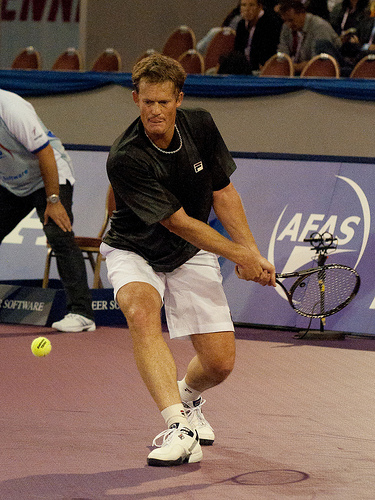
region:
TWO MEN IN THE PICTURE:
[8, 53, 261, 354]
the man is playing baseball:
[46, 79, 294, 434]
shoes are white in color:
[161, 396, 220, 456]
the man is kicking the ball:
[28, 151, 255, 354]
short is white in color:
[109, 244, 242, 342]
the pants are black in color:
[8, 192, 97, 265]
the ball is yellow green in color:
[30, 334, 78, 377]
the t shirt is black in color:
[144, 186, 235, 236]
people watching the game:
[233, 4, 356, 76]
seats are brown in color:
[276, 56, 332, 73]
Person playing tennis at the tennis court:
[95, 52, 361, 469]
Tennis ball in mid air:
[26, 334, 54, 358]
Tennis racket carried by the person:
[275, 260, 362, 319]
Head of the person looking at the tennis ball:
[128, 54, 189, 137]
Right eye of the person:
[140, 97, 155, 105]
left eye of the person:
[155, 97, 172, 105]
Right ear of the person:
[129, 89, 138, 104]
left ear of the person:
[174, 92, 184, 107]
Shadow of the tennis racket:
[205, 464, 313, 489]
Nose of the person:
[150, 102, 160, 115]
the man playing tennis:
[102, 54, 365, 470]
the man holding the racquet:
[96, 49, 374, 471]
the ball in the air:
[22, 329, 56, 363]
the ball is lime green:
[26, 333, 53, 360]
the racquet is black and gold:
[274, 262, 365, 325]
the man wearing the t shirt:
[95, 97, 250, 277]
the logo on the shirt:
[185, 157, 207, 175]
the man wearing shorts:
[96, 234, 238, 344]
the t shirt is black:
[106, 99, 237, 270]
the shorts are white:
[102, 236, 233, 339]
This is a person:
[113, 45, 294, 465]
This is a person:
[1, 82, 116, 360]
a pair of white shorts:
[97, 242, 235, 340]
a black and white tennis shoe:
[144, 425, 203, 467]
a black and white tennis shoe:
[175, 382, 215, 444]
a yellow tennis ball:
[29, 337, 50, 357]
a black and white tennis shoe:
[51, 313, 97, 332]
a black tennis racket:
[276, 266, 359, 317]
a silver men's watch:
[44, 193, 59, 205]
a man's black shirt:
[103, 109, 238, 277]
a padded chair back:
[12, 45, 41, 69]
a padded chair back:
[52, 48, 83, 71]